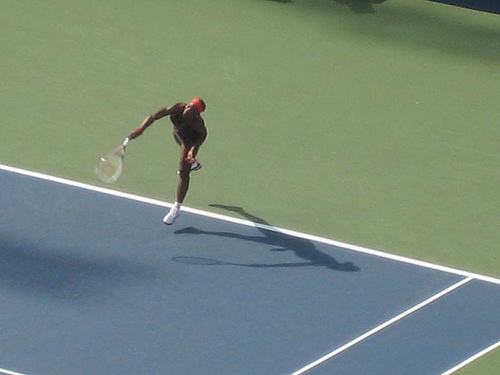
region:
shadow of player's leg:
[174, 221, 266, 247]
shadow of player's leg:
[207, 199, 280, 236]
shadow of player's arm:
[245, 260, 322, 267]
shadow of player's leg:
[271, 244, 286, 255]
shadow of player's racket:
[172, 253, 246, 266]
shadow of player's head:
[331, 255, 368, 275]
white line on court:
[263, 272, 480, 373]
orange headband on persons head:
[186, 97, 201, 107]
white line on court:
[6, 155, 493, 287]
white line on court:
[435, 341, 495, 373]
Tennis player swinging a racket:
[96, 96, 215, 221]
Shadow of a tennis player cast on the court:
[174, 197, 359, 276]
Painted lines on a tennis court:
[381, 244, 493, 323]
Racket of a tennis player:
[95, 137, 129, 183]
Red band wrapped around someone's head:
[191, 98, 204, 112]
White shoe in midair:
[163, 203, 183, 226]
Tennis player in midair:
[94, 96, 207, 225]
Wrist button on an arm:
[136, 126, 144, 136]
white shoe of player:
[162, 207, 183, 227]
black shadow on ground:
[172, 200, 356, 275]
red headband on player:
[191, 96, 206, 113]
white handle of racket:
[123, 137, 130, 147]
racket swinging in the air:
[92, 145, 123, 187]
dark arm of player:
[126, 102, 182, 142]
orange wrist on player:
[131, 124, 142, 136]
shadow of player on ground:
[172, 201, 361, 273]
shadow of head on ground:
[327, 250, 359, 277]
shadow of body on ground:
[277, 227, 334, 267]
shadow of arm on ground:
[235, 260, 316, 268]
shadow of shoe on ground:
[208, 201, 245, 213]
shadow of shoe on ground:
[170, 222, 197, 239]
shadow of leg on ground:
[198, 231, 277, 245]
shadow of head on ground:
[235, 202, 267, 230]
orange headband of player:
[188, 94, 205, 116]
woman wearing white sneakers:
[160, 204, 187, 226]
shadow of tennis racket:
[169, 244, 239, 273]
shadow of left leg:
[211, 192, 256, 222]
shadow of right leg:
[173, 227, 235, 244]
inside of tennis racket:
[103, 160, 118, 179]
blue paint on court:
[81, 274, 142, 314]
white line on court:
[23, 162, 53, 187]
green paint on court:
[57, 113, 89, 139]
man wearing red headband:
[194, 97, 204, 108]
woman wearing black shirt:
[177, 122, 189, 137]